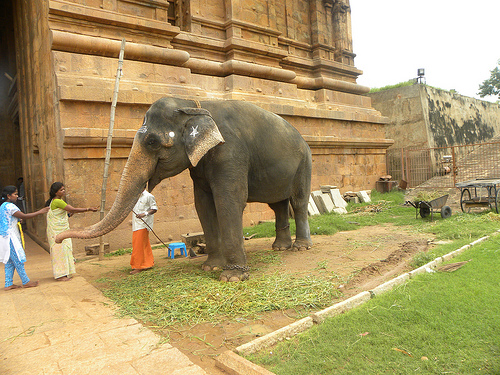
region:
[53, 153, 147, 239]
long brown trunk of elephant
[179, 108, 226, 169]
large brown ear of elephant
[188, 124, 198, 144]
white star on ear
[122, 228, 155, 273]
orange bottoms on woman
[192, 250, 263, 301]
large feet of elephant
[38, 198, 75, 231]
green shirt of woman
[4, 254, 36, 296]
blue pants on woman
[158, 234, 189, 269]
small blue stool on ground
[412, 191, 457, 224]
small wheel barrow on ground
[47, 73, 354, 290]
large grey elephant standing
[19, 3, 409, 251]
Ancient stone temple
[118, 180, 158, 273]
A man wearing white shirt and orange bottom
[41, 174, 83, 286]
A woman wearing saree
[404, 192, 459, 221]
Wheel burrow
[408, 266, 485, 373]
Green grass on the ground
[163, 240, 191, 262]
Small blue stool near elephant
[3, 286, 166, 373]
Stoned pavement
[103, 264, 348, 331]
Green fodder to feed an elephant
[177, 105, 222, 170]
White star on the elephant's ear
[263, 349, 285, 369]
green grass on ground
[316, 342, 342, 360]
green grass on ground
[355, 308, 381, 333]
green grass on ground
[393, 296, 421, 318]
green grass on ground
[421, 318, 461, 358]
green grass on ground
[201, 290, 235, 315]
green grass on ground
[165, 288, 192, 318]
green grass on ground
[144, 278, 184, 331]
green grass on ground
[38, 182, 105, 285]
woman in yellow or lime green shirt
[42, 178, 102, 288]
woman in light yellow sarong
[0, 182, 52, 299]
woman wearing white shirt with a blue design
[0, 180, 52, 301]
woman wearing blue pants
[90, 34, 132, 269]
long bamboo pole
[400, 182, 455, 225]
wheelbarrow full of grass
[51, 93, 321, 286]
large elephant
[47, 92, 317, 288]
large elephant with chains on one leg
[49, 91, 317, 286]
large grey elephant with white designs painted on his ear and face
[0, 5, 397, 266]
large brown stone ornamental building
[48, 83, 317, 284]
Elephant standing with chain around leg.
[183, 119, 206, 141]
White star painted on elephant's ear.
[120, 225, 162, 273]
Person dressed in orange Indian skirt.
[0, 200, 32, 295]
Woman dressed in white and blue Indian outfit.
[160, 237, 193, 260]
Blue stool sitting on ground.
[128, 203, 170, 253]
Man holding stick in hand.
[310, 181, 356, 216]
Concrete pavers stacked against wall.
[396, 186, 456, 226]
Wheel barrow behind elephant.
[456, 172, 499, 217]
Wood cart next to wheel barrow.